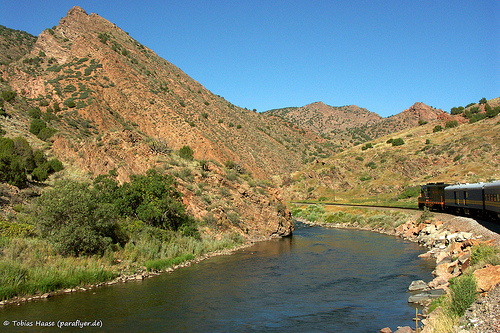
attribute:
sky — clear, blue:
[4, 2, 496, 122]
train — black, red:
[413, 178, 498, 213]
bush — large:
[33, 167, 201, 254]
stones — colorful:
[385, 222, 474, 331]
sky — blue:
[2, 0, 498, 98]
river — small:
[228, 206, 432, 327]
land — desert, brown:
[429, 215, 469, 246]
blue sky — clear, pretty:
[228, 29, 330, 89]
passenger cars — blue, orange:
[442, 178, 499, 218]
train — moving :
[416, 175, 498, 212]